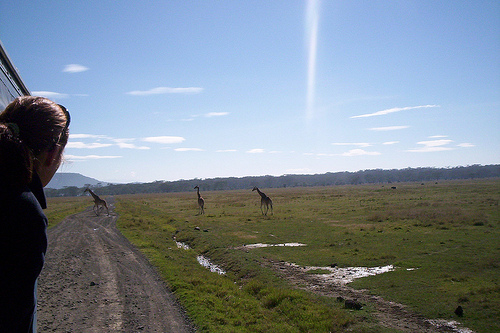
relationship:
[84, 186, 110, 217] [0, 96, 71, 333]
giraffe in front of woman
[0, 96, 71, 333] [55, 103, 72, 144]
woman has glasses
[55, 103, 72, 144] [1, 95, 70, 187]
glasses glassones head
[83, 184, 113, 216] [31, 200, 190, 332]
giraffe crossing road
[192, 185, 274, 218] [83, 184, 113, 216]
giraffes following giraffe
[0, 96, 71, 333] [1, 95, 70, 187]
woman has head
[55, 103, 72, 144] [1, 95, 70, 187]
sunglasses on head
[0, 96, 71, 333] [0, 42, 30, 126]
woman leaning out of bus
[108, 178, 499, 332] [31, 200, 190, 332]
field next to road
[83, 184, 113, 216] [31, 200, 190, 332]
giraffe on road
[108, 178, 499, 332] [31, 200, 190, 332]
field by road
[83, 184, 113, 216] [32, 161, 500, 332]
giraffe in habitat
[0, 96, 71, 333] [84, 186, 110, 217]
person looking at giraffe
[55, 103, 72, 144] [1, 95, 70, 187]
sunglasses on top of head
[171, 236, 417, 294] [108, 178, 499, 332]
water on field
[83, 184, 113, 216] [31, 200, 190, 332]
giraffe walking over road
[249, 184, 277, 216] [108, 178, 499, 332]
giraffe in field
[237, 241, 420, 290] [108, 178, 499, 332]
puddles in a field